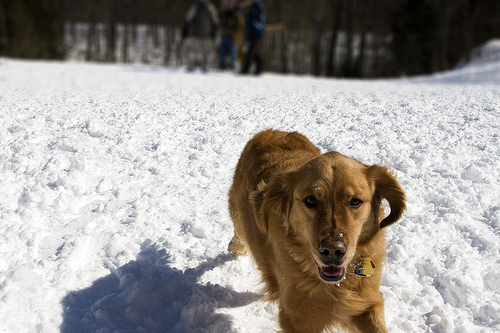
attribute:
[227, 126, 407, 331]
dog — facing ahead, brown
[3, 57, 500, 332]
snow — white, fluffy, sunlit, trampled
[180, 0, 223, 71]
person — standing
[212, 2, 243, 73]
person — standing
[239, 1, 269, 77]
person — standing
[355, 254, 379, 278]
tag — silver, name tag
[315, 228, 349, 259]
nose — brown, light brown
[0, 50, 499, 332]
ground — snowy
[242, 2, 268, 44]
jacket — blue, black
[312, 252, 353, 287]
mouth — open, small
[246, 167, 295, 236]
ear — curvy, floppy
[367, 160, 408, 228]
ear — curvy, floppy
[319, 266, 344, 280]
tongue — pink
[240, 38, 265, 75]
pants — black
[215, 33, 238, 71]
pants — blue